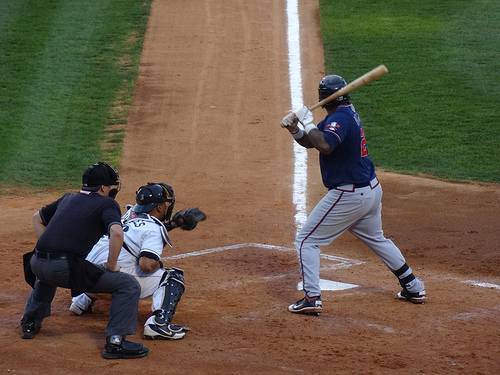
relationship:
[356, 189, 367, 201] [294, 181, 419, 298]
button in pant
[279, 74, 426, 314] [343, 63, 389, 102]
batter holding bat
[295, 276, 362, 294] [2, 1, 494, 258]
home plate on baseball field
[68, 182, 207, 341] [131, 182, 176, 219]
catcher wearing catchers mask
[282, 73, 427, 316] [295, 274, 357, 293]
batter on home plate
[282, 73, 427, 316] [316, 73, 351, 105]
batter has helmet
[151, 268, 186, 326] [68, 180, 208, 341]
protector on catcher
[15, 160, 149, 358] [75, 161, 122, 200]
umpire has face guard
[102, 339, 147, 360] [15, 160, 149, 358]
shoes of umpire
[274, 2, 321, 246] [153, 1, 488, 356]
line down dirt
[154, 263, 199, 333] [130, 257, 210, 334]
protector on leg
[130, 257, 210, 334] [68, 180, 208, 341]
leg of catcher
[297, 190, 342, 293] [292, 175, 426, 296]
stripes down pants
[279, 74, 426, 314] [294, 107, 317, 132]
batter wearing white gloves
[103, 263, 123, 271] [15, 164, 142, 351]
hand of a man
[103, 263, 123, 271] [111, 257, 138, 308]
hand on knee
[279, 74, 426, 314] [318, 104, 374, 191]
batter wearing shirt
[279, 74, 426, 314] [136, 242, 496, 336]
batter in batters box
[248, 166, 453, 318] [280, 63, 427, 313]
legs on player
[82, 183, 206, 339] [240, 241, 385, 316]
catcher behind plate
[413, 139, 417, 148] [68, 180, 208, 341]
ground behind catcher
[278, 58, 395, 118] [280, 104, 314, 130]
bat batters hands